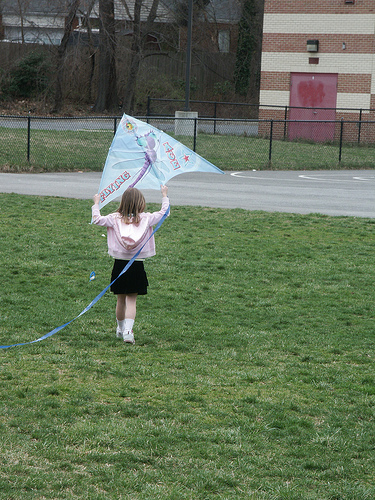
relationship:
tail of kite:
[9, 220, 171, 352] [92, 109, 218, 217]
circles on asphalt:
[354, 176, 373, 180] [0, 171, 373, 218]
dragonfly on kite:
[110, 129, 162, 188] [89, 111, 223, 210]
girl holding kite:
[91, 184, 170, 344] [88, 110, 225, 224]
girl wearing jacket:
[91, 184, 170, 344] [90, 197, 169, 261]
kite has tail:
[88, 110, 225, 224] [0, 204, 171, 349]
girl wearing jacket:
[77, 184, 173, 338] [90, 197, 170, 259]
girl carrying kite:
[91, 184, 170, 344] [89, 111, 223, 210]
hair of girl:
[103, 182, 145, 232] [59, 162, 203, 332]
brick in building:
[266, 1, 371, 14] [259, 0, 374, 147]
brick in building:
[264, 32, 303, 53] [259, 0, 374, 147]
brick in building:
[348, 32, 373, 54] [259, 0, 374, 147]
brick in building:
[260, 69, 287, 89] [259, 0, 374, 147]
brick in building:
[337, 72, 371, 91] [259, 0, 374, 147]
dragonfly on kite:
[127, 132, 161, 184] [52, 100, 268, 226]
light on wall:
[303, 37, 321, 54] [259, 1, 374, 146]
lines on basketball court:
[230, 167, 373, 191] [2, 168, 371, 237]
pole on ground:
[171, 105, 209, 137] [280, 200, 371, 243]